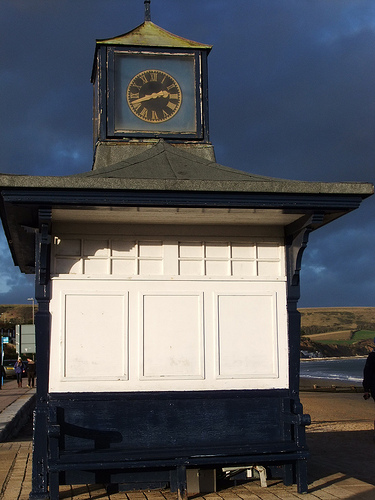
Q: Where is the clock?
A: Top of the building.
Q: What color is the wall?
A: White.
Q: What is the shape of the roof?
A: Pointed.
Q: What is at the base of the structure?
A: Bench.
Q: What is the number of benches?
A: One.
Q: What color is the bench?
A: Black.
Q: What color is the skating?
A: Blue.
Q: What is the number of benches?
A: One.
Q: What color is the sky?
A: Blue.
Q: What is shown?
A: Clock tower.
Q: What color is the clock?
A: Black.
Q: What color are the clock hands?
A: Gold.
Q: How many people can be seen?
A: 2.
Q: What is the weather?
A: Overcast.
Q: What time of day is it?
A: Daytime.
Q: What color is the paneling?
A: White.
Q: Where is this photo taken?
A: In front of a clock.